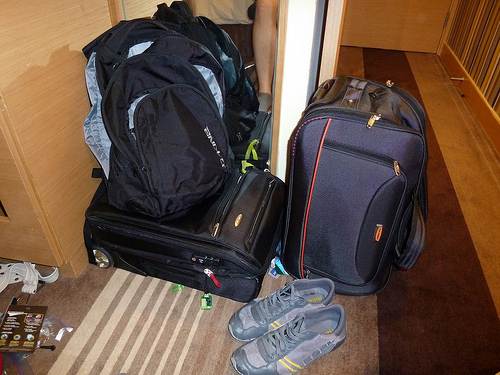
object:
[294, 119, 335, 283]
stripe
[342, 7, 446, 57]
door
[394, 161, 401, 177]
zipper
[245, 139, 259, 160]
tag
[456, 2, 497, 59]
wall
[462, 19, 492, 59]
stripes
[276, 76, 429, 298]
backpack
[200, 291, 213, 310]
tag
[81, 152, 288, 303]
bag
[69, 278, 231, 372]
floor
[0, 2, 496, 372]
room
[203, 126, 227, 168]
sign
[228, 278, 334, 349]
shoes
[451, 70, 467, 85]
metal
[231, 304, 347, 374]
shoe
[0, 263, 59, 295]
white belt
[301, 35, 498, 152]
floor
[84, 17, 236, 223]
backpack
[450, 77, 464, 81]
door stop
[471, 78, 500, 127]
wall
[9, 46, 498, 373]
ground